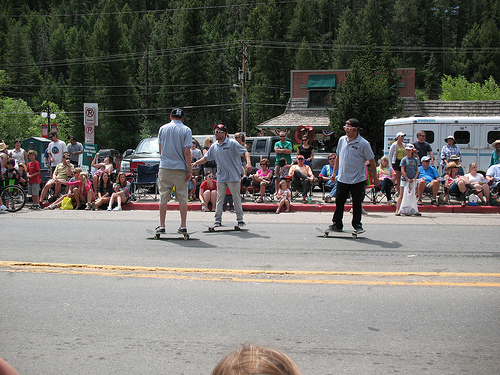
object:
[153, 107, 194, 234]
person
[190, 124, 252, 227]
person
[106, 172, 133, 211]
person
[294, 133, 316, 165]
person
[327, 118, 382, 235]
person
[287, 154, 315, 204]
person